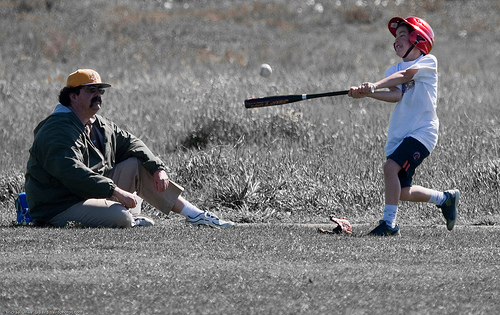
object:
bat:
[244, 85, 376, 109]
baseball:
[259, 63, 272, 77]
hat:
[67, 68, 112, 89]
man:
[21, 65, 242, 228]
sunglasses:
[79, 86, 106, 95]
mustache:
[88, 96, 104, 108]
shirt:
[379, 56, 439, 155]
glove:
[317, 215, 355, 234]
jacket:
[21, 100, 164, 223]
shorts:
[380, 137, 431, 188]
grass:
[1, 222, 499, 314]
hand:
[349, 86, 364, 99]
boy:
[350, 15, 461, 237]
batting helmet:
[388, 15, 433, 57]